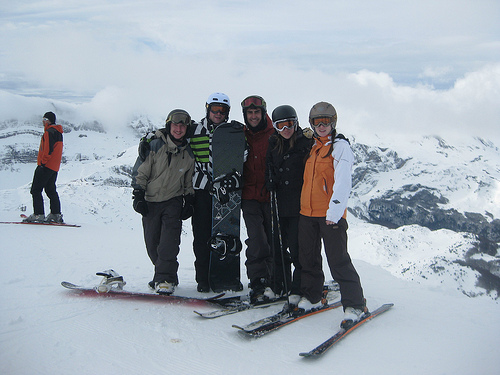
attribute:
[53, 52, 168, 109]
clouds — white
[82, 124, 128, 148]
sky — blue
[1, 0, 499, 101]
sky — blue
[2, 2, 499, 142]
clouds — white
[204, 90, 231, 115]
helmet — white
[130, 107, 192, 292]
person — posing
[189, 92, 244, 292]
person — posing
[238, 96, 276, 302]
person — posing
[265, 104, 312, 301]
person — posing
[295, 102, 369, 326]
person — posing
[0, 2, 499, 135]
sky — blue, white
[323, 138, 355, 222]
arm — white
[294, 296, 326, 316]
boot — white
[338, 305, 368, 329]
boot — white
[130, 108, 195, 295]
man — smiling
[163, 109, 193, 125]
goggles — brown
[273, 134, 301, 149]
hair — brown, long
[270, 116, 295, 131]
goggles — silver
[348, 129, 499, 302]
mountain — snowy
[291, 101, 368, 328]
woman — wearing an orange and white jacket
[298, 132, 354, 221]
jacket — orange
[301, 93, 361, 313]
woman — wearing a jacket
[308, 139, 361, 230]
jacket — orange, white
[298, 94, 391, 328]
woman — wearing an orange and white jacket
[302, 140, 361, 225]
jacket — orange and white jacket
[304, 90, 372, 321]
woman — wearing a helmet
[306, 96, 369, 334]
woman — wearing a helmet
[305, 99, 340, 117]
ski helmet — grey safety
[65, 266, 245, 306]
snow board — grey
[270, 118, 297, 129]
ski goggles — white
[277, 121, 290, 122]
lens — amber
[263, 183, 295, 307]
poles — black, grey, ski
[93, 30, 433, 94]
area — mountainous , behind the skiers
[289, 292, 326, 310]
boots — white, mounted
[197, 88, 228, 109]
helmet — white, safety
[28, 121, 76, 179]
jacket — orange, blue, ski